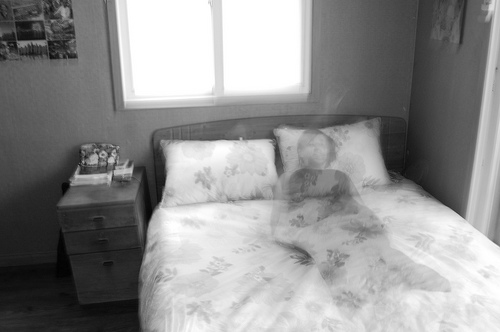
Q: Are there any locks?
A: No, there are no locks.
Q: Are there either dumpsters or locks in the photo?
A: No, there are no locks or dumpsters.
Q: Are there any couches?
A: No, there are no couches.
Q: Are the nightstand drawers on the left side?
A: Yes, the drawers are on the left of the image.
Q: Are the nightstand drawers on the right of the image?
A: No, the drawers are on the left of the image.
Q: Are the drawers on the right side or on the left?
A: The drawers are on the left of the image.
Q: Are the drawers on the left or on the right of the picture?
A: The drawers are on the left of the image.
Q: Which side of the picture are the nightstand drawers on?
A: The drawers are on the left of the image.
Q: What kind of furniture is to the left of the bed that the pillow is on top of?
A: The pieces of furniture are drawers.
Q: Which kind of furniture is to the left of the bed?
A: The pieces of furniture are drawers.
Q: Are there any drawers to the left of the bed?
A: Yes, there are drawers to the left of the bed.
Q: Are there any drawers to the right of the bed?
A: No, the drawers are to the left of the bed.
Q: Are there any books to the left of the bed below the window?
A: No, there are drawers to the left of the bed.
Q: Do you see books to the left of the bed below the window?
A: No, there are drawers to the left of the bed.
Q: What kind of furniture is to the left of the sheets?
A: The pieces of furniture are drawers.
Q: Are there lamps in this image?
A: No, there are no lamps.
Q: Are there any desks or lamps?
A: No, there are no lamps or desks.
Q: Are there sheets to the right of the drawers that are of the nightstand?
A: Yes, there are sheets to the right of the drawers.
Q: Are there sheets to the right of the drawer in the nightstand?
A: Yes, there are sheets to the right of the drawer.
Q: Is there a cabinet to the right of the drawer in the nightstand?
A: No, there are sheets to the right of the drawer.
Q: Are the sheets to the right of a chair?
A: No, the sheets are to the right of a drawer.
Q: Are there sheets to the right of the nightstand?
A: Yes, there are sheets to the right of the nightstand.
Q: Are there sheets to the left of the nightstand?
A: No, the sheets are to the right of the nightstand.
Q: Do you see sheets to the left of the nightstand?
A: No, the sheets are to the right of the nightstand.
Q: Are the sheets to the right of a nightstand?
A: Yes, the sheets are to the right of a nightstand.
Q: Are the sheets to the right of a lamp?
A: No, the sheets are to the right of a nightstand.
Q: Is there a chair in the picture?
A: No, there are no chairs.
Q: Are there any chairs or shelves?
A: No, there are no chairs or shelves.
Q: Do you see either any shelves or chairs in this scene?
A: No, there are no chairs or shelves.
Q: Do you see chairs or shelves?
A: No, there are no chairs or shelves.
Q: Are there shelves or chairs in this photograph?
A: No, there are no chairs or shelves.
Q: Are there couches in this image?
A: No, there are no couches.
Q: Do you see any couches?
A: No, there are no couches.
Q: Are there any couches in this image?
A: No, there are no couches.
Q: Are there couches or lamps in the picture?
A: No, there are no couches or lamps.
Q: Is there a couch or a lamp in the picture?
A: No, there are no couches or lamps.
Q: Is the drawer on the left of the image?
A: Yes, the drawer is on the left of the image.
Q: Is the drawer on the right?
A: No, the drawer is on the left of the image.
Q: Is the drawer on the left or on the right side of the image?
A: The drawer is on the left of the image.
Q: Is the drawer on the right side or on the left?
A: The drawer is on the left of the image.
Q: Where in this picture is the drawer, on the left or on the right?
A: The drawer is on the left of the image.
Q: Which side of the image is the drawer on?
A: The drawer is on the left of the image.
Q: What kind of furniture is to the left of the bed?
A: The piece of furniture is a drawer.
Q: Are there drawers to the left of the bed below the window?
A: Yes, there is a drawer to the left of the bed.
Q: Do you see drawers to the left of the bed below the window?
A: Yes, there is a drawer to the left of the bed.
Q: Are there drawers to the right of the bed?
A: No, the drawer is to the left of the bed.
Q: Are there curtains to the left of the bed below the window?
A: No, there is a drawer to the left of the bed.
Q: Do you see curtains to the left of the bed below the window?
A: No, there is a drawer to the left of the bed.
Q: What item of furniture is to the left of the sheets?
A: The piece of furniture is a drawer.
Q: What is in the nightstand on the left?
A: The drawer is in the nightstand.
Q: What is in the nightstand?
A: The drawer is in the nightstand.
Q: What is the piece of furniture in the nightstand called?
A: The piece of furniture is a drawer.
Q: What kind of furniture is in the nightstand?
A: The piece of furniture is a drawer.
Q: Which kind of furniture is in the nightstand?
A: The piece of furniture is a drawer.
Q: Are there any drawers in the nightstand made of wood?
A: Yes, there is a drawer in the nightstand.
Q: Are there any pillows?
A: Yes, there is a pillow.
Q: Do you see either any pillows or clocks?
A: Yes, there is a pillow.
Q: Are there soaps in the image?
A: No, there are no soaps.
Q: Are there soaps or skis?
A: No, there are no soaps or skis.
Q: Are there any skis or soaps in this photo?
A: No, there are no soaps or skis.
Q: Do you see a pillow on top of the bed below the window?
A: Yes, there is a pillow on top of the bed.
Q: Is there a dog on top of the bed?
A: No, there is a pillow on top of the bed.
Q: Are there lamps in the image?
A: No, there are no lamps.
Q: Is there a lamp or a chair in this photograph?
A: No, there are no lamps or chairs.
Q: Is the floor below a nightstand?
A: Yes, the floor is below a nightstand.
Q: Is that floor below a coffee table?
A: No, the floor is below a nightstand.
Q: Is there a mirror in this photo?
A: No, there are no mirrors.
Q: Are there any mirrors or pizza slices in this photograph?
A: No, there are no mirrors or pizza slices.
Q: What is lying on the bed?
A: The figure is lying on the bed.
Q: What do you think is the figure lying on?
A: The figure is lying on the bed.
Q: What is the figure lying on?
A: The figure is lying on the bed.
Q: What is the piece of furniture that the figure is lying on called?
A: The piece of furniture is a bed.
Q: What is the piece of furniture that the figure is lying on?
A: The piece of furniture is a bed.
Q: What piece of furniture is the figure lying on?
A: The figure is lying on the bed.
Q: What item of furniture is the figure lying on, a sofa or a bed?
A: The figure is lying on a bed.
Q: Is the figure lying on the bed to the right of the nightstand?
A: Yes, the figure is lying on the bed.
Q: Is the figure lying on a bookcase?
A: No, the figure is lying on the bed.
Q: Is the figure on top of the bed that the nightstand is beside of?
A: Yes, the figure is on top of the bed.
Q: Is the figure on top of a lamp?
A: No, the figure is on top of the bed.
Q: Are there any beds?
A: Yes, there is a bed.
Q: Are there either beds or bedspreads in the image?
A: Yes, there is a bed.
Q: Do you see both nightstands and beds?
A: Yes, there are both a bed and a nightstand.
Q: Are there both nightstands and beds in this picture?
A: Yes, there are both a bed and a nightstand.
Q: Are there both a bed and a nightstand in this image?
A: Yes, there are both a bed and a nightstand.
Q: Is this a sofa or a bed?
A: This is a bed.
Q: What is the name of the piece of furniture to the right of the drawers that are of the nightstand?
A: The piece of furniture is a bed.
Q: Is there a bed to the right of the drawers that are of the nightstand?
A: Yes, there is a bed to the right of the drawers.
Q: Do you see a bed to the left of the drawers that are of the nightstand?
A: No, the bed is to the right of the drawers.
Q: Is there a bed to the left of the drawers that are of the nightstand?
A: No, the bed is to the right of the drawers.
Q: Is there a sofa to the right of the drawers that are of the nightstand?
A: No, there is a bed to the right of the drawers.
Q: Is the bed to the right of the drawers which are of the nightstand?
A: Yes, the bed is to the right of the drawers.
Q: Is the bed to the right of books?
A: No, the bed is to the right of the drawers.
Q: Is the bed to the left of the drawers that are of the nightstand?
A: No, the bed is to the right of the drawers.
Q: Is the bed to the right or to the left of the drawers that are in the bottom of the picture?
A: The bed is to the right of the drawers.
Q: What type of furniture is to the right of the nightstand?
A: The piece of furniture is a bed.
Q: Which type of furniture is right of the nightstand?
A: The piece of furniture is a bed.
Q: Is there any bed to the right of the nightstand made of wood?
A: Yes, there is a bed to the right of the nightstand.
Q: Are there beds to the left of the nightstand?
A: No, the bed is to the right of the nightstand.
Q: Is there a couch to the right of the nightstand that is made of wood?
A: No, there is a bed to the right of the nightstand.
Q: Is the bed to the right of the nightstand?
A: Yes, the bed is to the right of the nightstand.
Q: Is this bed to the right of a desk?
A: No, the bed is to the right of the nightstand.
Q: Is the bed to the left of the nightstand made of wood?
A: No, the bed is to the right of the nightstand.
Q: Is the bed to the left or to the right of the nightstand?
A: The bed is to the right of the nightstand.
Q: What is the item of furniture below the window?
A: The piece of furniture is a bed.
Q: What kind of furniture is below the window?
A: The piece of furniture is a bed.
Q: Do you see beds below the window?
A: Yes, there is a bed below the window.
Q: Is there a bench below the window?
A: No, there is a bed below the window.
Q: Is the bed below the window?
A: Yes, the bed is below the window.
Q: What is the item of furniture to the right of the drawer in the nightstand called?
A: The piece of furniture is a bed.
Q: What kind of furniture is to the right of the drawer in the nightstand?
A: The piece of furniture is a bed.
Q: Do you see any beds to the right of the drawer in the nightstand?
A: Yes, there is a bed to the right of the drawer.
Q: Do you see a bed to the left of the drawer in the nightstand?
A: No, the bed is to the right of the drawer.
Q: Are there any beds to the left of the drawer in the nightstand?
A: No, the bed is to the right of the drawer.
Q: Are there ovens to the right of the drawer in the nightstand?
A: No, there is a bed to the right of the drawer.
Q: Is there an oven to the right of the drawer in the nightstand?
A: No, there is a bed to the right of the drawer.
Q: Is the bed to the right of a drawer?
A: Yes, the bed is to the right of a drawer.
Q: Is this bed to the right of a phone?
A: No, the bed is to the right of a drawer.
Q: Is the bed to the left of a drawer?
A: No, the bed is to the right of a drawer.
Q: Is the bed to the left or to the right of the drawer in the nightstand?
A: The bed is to the right of the drawer.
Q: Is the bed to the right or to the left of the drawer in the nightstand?
A: The bed is to the right of the drawer.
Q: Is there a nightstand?
A: Yes, there is a nightstand.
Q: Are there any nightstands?
A: Yes, there is a nightstand.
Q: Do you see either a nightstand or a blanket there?
A: Yes, there is a nightstand.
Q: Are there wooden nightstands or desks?
A: Yes, there is a wood nightstand.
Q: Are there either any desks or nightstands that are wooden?
A: Yes, the nightstand is wooden.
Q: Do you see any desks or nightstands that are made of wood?
A: Yes, the nightstand is made of wood.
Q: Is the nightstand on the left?
A: Yes, the nightstand is on the left of the image.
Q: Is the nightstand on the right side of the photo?
A: No, the nightstand is on the left of the image.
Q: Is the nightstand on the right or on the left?
A: The nightstand is on the left of the image.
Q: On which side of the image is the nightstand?
A: The nightstand is on the left of the image.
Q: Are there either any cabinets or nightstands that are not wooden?
A: No, there is a nightstand but it is wooden.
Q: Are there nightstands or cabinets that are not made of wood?
A: No, there is a nightstand but it is made of wood.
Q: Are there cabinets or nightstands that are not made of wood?
A: No, there is a nightstand but it is made of wood.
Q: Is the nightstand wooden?
A: Yes, the nightstand is wooden.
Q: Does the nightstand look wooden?
A: Yes, the nightstand is wooden.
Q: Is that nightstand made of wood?
A: Yes, the nightstand is made of wood.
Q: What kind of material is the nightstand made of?
A: The nightstand is made of wood.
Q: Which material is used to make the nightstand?
A: The nightstand is made of wood.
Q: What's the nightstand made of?
A: The nightstand is made of wood.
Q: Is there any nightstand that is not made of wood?
A: No, there is a nightstand but it is made of wood.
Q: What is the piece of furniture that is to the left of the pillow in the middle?
A: The piece of furniture is a nightstand.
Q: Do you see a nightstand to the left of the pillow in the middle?
A: Yes, there is a nightstand to the left of the pillow.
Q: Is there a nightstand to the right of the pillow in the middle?
A: No, the nightstand is to the left of the pillow.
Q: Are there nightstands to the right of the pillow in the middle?
A: No, the nightstand is to the left of the pillow.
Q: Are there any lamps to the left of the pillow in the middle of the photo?
A: No, there is a nightstand to the left of the pillow.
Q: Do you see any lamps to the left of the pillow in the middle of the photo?
A: No, there is a nightstand to the left of the pillow.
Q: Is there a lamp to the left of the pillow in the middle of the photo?
A: No, there is a nightstand to the left of the pillow.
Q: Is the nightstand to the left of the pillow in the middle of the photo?
A: Yes, the nightstand is to the left of the pillow.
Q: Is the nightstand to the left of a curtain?
A: No, the nightstand is to the left of the pillow.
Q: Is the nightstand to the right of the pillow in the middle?
A: No, the nightstand is to the left of the pillow.